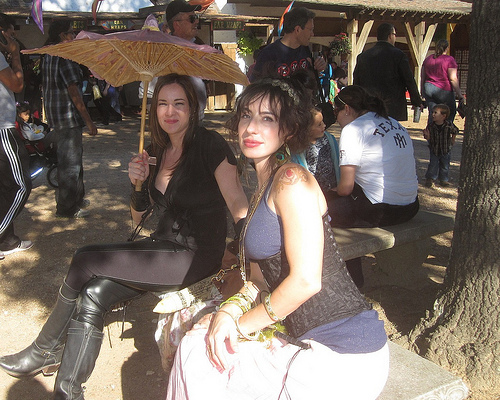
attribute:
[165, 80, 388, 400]
woman — staring, light skinned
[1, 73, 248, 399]
woman — staring, light skinned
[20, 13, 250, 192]
umbrella — brown, straw, tan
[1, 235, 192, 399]
legs — crossed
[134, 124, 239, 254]
blouse — black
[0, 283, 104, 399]
boots — black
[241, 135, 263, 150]
lips — red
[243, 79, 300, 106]
headband — floral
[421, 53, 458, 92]
shirt — fuchsia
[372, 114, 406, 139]
print — black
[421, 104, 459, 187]
boy — small, standing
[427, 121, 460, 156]
shirt — plaid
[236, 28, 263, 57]
leaves — green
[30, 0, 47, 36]
flag — purple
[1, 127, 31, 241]
pants — black, striped, white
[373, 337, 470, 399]
bench — stone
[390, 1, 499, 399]
tree — brown, sunny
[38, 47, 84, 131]
shirt — plaid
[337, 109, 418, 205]
shirt — white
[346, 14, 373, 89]
support post — wooden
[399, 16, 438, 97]
support post — wooden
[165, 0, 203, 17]
cap — black